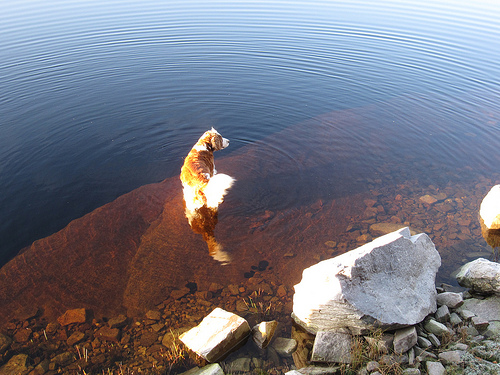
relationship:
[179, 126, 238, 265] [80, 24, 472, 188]
dog in water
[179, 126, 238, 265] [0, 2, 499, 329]
dog in water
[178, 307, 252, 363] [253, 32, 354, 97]
rock in water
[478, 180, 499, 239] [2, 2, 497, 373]
rock in water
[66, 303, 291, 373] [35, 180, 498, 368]
grass growing in rocks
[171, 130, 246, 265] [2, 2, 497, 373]
dog swimming in water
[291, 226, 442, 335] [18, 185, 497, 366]
rock on shore